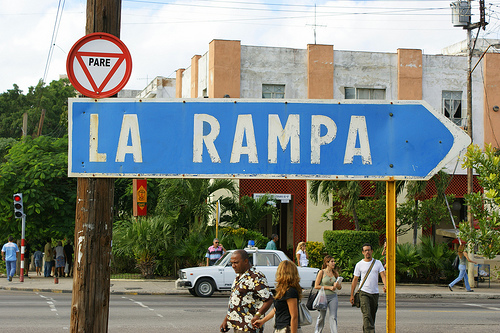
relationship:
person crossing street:
[341, 240, 391, 331] [2, 271, 499, 330]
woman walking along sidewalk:
[447, 239, 477, 298] [0, 267, 498, 296]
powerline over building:
[121, 0, 495, 17] [133, 41, 500, 279]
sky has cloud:
[4, 1, 499, 87] [10, 4, 493, 89]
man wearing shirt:
[216, 247, 272, 330] [227, 271, 271, 330]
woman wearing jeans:
[300, 252, 356, 331] [313, 293, 341, 331]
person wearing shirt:
[341, 240, 391, 331] [353, 256, 385, 293]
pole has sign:
[67, 1, 122, 331] [64, 30, 134, 99]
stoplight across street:
[12, 189, 28, 226] [2, 271, 499, 330]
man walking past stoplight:
[2, 236, 22, 286] [12, 189, 28, 226]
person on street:
[341, 240, 391, 331] [2, 271, 499, 330]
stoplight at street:
[12, 189, 28, 226] [2, 271, 499, 330]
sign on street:
[64, 30, 134, 99] [2, 271, 499, 330]